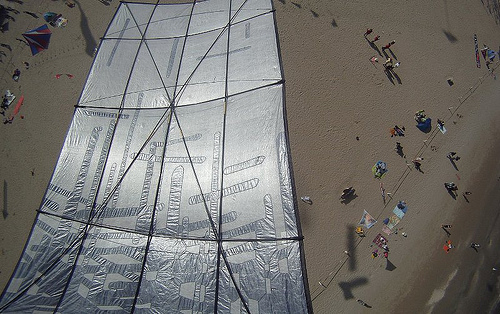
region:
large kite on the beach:
[57, 32, 317, 312]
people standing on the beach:
[361, 21, 403, 51]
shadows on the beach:
[328, 216, 367, 309]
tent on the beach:
[27, 23, 61, 49]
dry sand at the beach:
[303, 51, 353, 141]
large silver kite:
[93, 50, 248, 223]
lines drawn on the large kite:
[82, 122, 262, 309]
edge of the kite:
[277, 75, 298, 185]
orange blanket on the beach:
[438, 234, 463, 254]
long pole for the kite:
[162, 95, 234, 286]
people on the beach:
[308, 33, 496, 275]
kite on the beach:
[358, 210, 379, 234]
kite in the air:
[8, 0, 313, 312]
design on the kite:
[9, 2, 314, 312]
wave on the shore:
[424, 263, 470, 311]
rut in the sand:
[295, 73, 485, 303]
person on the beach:
[409, 152, 430, 171]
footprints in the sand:
[280, 79, 388, 177]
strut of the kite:
[61, 69, 281, 124]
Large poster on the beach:
[0, 2, 314, 312]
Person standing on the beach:
[365, 20, 373, 37]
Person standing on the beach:
[384, 37, 394, 50]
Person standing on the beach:
[441, 220, 454, 231]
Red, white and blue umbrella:
[19, 25, 59, 56]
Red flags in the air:
[51, 68, 77, 85]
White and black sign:
[0, 0, 315, 312]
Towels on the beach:
[367, 196, 411, 254]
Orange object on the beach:
[13, 91, 27, 120]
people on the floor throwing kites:
[354, 19, 402, 76]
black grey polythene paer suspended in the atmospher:
[136, 229, 253, 312]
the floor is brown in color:
[319, 83, 346, 146]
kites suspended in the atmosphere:
[393, 102, 445, 176]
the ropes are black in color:
[181, 214, 243, 248]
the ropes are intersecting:
[203, 213, 250, 275]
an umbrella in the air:
[13, 28, 54, 49]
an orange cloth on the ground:
[443, 238, 465, 252]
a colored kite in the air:
[351, 204, 385, 235]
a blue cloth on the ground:
[418, 117, 438, 131]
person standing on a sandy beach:
[360, 23, 377, 42]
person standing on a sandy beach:
[369, 30, 386, 49]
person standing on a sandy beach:
[377, 37, 396, 53]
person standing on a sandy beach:
[391, 58, 403, 73]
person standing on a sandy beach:
[410, 153, 428, 164]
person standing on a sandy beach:
[339, 183, 358, 200]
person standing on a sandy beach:
[450, 150, 465, 166]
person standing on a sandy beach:
[442, 175, 457, 190]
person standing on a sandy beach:
[438, 219, 455, 232]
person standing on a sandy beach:
[469, 238, 482, 251]